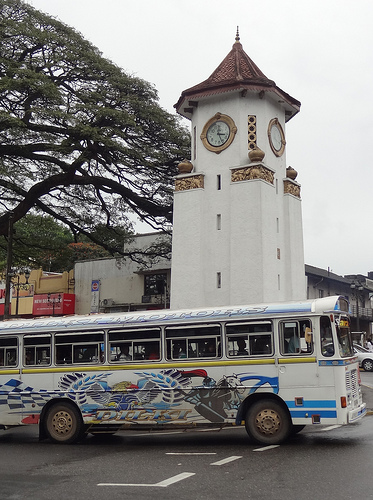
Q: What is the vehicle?
A: A bus.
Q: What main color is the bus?
A: White.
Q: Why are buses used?
A: To transport.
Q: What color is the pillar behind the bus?
A: White and gold.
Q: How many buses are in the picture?
A: 1.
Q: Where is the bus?
A: In the street.